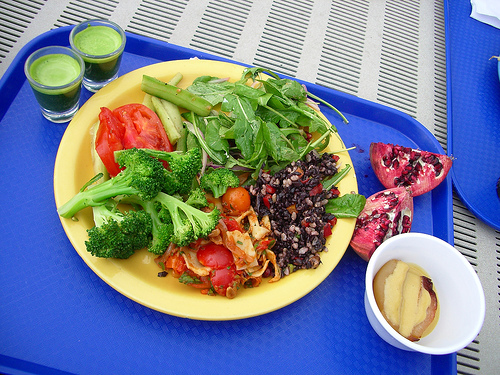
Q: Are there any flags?
A: No, there are no flags.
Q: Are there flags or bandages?
A: No, there are no flags or bandages.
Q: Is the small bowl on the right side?
A: Yes, the bowl is on the right of the image.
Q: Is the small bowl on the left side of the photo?
A: No, the bowl is on the right of the image.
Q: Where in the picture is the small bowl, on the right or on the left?
A: The bowl is on the right of the image.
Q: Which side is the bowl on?
A: The bowl is on the right of the image.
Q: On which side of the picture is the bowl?
A: The bowl is on the right of the image.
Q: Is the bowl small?
A: Yes, the bowl is small.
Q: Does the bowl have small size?
A: Yes, the bowl is small.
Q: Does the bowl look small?
A: Yes, the bowl is small.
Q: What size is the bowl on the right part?
A: The bowl is small.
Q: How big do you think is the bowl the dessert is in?
A: The bowl is small.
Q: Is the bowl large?
A: No, the bowl is small.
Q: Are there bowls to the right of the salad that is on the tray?
A: Yes, there is a bowl to the right of the salad.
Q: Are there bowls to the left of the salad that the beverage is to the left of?
A: No, the bowl is to the right of the salad.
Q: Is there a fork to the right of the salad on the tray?
A: No, there is a bowl to the right of the salad.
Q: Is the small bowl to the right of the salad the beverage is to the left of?
A: Yes, the bowl is to the right of the salad.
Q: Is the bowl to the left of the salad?
A: No, the bowl is to the right of the salad.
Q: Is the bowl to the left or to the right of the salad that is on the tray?
A: The bowl is to the right of the salad.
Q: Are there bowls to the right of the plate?
A: Yes, there is a bowl to the right of the plate.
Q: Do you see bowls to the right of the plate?
A: Yes, there is a bowl to the right of the plate.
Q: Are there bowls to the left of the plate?
A: No, the bowl is to the right of the plate.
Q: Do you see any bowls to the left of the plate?
A: No, the bowl is to the right of the plate.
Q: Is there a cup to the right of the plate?
A: No, there is a bowl to the right of the plate.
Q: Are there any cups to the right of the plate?
A: No, there is a bowl to the right of the plate.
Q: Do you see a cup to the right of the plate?
A: No, there is a bowl to the right of the plate.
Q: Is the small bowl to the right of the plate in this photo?
A: Yes, the bowl is to the right of the plate.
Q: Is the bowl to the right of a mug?
A: No, the bowl is to the right of the plate.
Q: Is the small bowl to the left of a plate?
A: No, the bowl is to the right of a plate.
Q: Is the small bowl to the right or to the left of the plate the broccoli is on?
A: The bowl is to the right of the plate.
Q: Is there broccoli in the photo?
A: Yes, there is broccoli.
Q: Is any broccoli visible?
A: Yes, there is broccoli.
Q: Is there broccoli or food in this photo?
A: Yes, there is broccoli.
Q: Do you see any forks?
A: No, there are no forks.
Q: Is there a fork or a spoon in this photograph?
A: No, there are no forks or spoons.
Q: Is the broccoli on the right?
A: No, the broccoli is on the left of the image.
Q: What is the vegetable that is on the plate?
A: The vegetable is broccoli.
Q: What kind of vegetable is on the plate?
A: The vegetable is broccoli.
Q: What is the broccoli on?
A: The broccoli is on the plate.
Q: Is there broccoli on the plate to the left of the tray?
A: Yes, there is broccoli on the plate.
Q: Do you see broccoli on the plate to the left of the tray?
A: Yes, there is broccoli on the plate.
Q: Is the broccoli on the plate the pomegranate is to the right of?
A: Yes, the broccoli is on the plate.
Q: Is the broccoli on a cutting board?
A: No, the broccoli is on the plate.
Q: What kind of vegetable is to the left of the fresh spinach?
A: The vegetable is broccoli.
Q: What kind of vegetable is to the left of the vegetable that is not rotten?
A: The vegetable is broccoli.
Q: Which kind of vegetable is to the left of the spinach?
A: The vegetable is broccoli.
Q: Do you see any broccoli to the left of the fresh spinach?
A: Yes, there is broccoli to the left of the spinach.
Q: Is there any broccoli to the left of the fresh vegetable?
A: Yes, there is broccoli to the left of the spinach.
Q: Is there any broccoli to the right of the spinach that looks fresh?
A: No, the broccoli is to the left of the spinach.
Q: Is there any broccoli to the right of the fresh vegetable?
A: No, the broccoli is to the left of the spinach.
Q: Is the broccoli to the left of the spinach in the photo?
A: Yes, the broccoli is to the left of the spinach.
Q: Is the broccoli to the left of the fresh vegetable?
A: Yes, the broccoli is to the left of the spinach.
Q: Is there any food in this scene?
A: Yes, there is food.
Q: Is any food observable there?
A: Yes, there is food.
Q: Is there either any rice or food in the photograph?
A: Yes, there is food.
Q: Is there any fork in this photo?
A: No, there are no forks.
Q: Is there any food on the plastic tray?
A: Yes, there is food on the tray.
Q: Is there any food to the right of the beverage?
A: Yes, there is food to the right of the beverage.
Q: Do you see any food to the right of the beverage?
A: Yes, there is food to the right of the beverage.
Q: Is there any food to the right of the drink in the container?
A: Yes, there is food to the right of the beverage.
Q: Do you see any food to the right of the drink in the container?
A: Yes, there is food to the right of the beverage.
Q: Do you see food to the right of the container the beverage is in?
A: Yes, there is food to the right of the container.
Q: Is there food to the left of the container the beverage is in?
A: No, the food is to the right of the container.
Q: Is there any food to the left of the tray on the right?
A: Yes, there is food to the left of the tray.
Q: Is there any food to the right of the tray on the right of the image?
A: No, the food is to the left of the tray.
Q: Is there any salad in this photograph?
A: Yes, there is salad.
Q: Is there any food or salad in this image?
A: Yes, there is salad.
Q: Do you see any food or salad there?
A: Yes, there is salad.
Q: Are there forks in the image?
A: No, there are no forks.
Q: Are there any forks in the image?
A: No, there are no forks.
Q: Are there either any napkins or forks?
A: No, there are no forks or napkins.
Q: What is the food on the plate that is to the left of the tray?
A: The food is salad.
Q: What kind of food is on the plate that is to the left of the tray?
A: The food is salad.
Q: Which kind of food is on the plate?
A: The food is salad.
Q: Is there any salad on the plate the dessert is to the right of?
A: Yes, there is salad on the plate.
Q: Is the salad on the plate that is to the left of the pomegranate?
A: Yes, the salad is on the plate.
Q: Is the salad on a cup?
A: No, the salad is on the plate.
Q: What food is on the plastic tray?
A: The food is salad.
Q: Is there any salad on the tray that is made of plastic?
A: Yes, there is salad on the tray.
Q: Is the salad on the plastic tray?
A: Yes, the salad is on the tray.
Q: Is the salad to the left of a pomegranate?
A: Yes, the salad is to the left of a pomegranate.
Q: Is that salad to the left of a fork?
A: No, the salad is to the left of a pomegranate.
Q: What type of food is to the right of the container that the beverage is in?
A: The food is salad.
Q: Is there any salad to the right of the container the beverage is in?
A: Yes, there is salad to the right of the container.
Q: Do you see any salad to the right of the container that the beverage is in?
A: Yes, there is salad to the right of the container.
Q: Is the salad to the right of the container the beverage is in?
A: Yes, the salad is to the right of the container.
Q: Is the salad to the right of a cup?
A: No, the salad is to the right of the container.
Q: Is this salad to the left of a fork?
A: No, the salad is to the left of a pomegranate.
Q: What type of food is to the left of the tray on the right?
A: The food is salad.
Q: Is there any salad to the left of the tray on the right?
A: Yes, there is salad to the left of the tray.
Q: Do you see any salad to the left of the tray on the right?
A: Yes, there is salad to the left of the tray.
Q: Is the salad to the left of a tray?
A: Yes, the salad is to the left of a tray.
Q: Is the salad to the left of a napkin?
A: No, the salad is to the left of a tray.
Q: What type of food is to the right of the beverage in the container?
A: The food is salad.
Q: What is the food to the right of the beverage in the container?
A: The food is salad.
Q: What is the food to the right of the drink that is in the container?
A: The food is salad.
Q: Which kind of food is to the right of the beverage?
A: The food is salad.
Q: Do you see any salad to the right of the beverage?
A: Yes, there is salad to the right of the beverage.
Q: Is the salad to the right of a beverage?
A: Yes, the salad is to the right of a beverage.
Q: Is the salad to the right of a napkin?
A: No, the salad is to the right of a beverage.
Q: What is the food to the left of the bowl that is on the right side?
A: The food is salad.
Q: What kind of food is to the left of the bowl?
A: The food is salad.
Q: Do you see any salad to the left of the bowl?
A: Yes, there is salad to the left of the bowl.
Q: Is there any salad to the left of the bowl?
A: Yes, there is salad to the left of the bowl.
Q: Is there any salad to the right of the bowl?
A: No, the salad is to the left of the bowl.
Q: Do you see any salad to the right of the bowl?
A: No, the salad is to the left of the bowl.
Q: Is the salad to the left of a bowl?
A: Yes, the salad is to the left of a bowl.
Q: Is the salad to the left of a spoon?
A: No, the salad is to the left of a bowl.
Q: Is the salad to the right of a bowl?
A: No, the salad is to the left of a bowl.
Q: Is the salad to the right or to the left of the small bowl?
A: The salad is to the left of the bowl.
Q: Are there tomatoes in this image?
A: Yes, there is a tomato.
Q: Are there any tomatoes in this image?
A: Yes, there is a tomato.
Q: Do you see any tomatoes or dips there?
A: Yes, there is a tomato.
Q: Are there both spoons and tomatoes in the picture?
A: No, there is a tomato but no spoons.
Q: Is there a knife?
A: No, there are no knives.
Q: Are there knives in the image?
A: No, there are no knives.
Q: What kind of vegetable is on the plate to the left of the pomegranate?
A: The vegetable is a tomato.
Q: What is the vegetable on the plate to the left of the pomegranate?
A: The vegetable is a tomato.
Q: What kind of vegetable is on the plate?
A: The vegetable is a tomato.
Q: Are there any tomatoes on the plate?
A: Yes, there is a tomato on the plate.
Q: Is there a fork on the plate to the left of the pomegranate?
A: No, there is a tomato on the plate.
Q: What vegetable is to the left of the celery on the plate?
A: The vegetable is a tomato.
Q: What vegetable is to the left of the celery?
A: The vegetable is a tomato.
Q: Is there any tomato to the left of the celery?
A: Yes, there is a tomato to the left of the celery.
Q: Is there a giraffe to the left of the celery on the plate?
A: No, there is a tomato to the left of the celery.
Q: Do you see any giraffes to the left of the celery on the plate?
A: No, there is a tomato to the left of the celery.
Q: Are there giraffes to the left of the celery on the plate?
A: No, there is a tomato to the left of the celery.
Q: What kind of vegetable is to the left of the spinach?
A: The vegetable is a tomato.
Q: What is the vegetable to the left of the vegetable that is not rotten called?
A: The vegetable is a tomato.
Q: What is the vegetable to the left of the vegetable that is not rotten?
A: The vegetable is a tomato.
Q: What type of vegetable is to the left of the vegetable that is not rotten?
A: The vegetable is a tomato.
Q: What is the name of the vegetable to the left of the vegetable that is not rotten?
A: The vegetable is a tomato.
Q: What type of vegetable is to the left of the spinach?
A: The vegetable is a tomato.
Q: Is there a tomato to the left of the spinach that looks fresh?
A: Yes, there is a tomato to the left of the spinach.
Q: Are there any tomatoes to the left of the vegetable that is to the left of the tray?
A: Yes, there is a tomato to the left of the spinach.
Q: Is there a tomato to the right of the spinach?
A: No, the tomato is to the left of the spinach.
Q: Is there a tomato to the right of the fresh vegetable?
A: No, the tomato is to the left of the spinach.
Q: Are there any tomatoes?
A: Yes, there is a tomato.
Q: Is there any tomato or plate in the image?
A: Yes, there is a tomato.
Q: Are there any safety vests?
A: No, there are no safety vests.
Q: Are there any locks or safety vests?
A: No, there are no safety vests or locks.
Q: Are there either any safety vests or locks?
A: No, there are no safety vests or locks.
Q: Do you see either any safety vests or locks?
A: No, there are no safety vests or locks.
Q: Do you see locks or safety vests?
A: No, there are no safety vests or locks.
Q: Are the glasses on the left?
A: Yes, the glasses are on the left of the image.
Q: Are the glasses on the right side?
A: No, the glasses are on the left of the image.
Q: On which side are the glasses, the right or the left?
A: The glasses are on the left of the image.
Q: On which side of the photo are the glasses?
A: The glasses are on the left of the image.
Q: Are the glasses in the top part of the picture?
A: Yes, the glasses are in the top of the image.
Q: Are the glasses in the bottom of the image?
A: No, the glasses are in the top of the image.